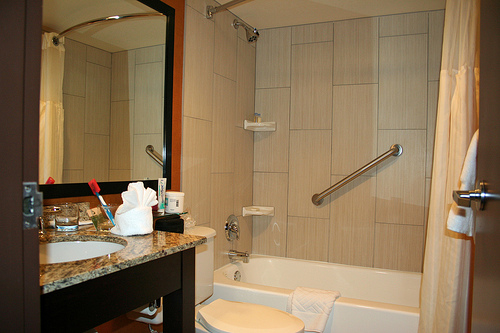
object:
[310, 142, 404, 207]
rail bar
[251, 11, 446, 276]
shower wall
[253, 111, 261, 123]
bottle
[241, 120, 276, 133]
shelf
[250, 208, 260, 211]
soap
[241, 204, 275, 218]
shelf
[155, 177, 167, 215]
toothpaste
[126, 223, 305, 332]
toilet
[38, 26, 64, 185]
shower curtain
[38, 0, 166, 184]
mirror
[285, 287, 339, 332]
towel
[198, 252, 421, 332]
bathtub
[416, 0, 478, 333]
shower curtain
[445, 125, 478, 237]
towel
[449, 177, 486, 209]
door handle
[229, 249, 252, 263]
faucet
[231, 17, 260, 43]
shower head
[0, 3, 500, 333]
bathroom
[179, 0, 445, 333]
shower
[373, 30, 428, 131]
tile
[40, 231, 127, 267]
sink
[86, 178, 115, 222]
toothbrush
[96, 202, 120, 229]
glass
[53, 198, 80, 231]
glass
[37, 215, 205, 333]
counter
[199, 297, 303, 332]
seat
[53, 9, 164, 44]
curtain rod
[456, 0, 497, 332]
door